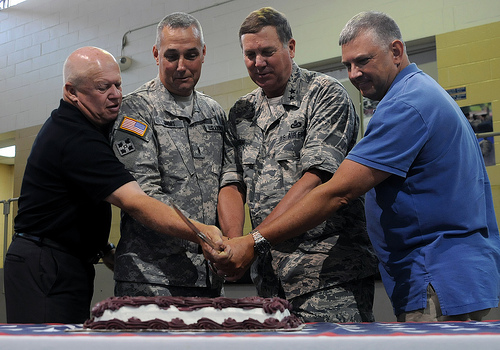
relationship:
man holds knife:
[4, 42, 226, 317] [171, 204, 220, 252]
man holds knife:
[109, 12, 226, 298] [171, 204, 220, 252]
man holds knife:
[218, 6, 380, 323] [171, 204, 220, 252]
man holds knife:
[212, 13, 500, 324] [171, 204, 220, 252]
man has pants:
[4, 51, 240, 300] [1, 235, 98, 325]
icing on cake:
[86, 285, 301, 339] [66, 267, 310, 334]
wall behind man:
[6, 2, 494, 309] [212, 13, 500, 324]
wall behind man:
[6, 2, 494, 309] [4, 42, 226, 317]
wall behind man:
[6, 2, 494, 309] [109, 12, 226, 298]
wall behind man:
[6, 2, 494, 309] [218, 6, 380, 323]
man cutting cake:
[212, 13, 500, 324] [83, 295, 307, 330]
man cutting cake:
[218, 6, 380, 323] [83, 295, 307, 330]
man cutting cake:
[109, 12, 226, 298] [83, 295, 307, 330]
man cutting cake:
[2, 46, 226, 323] [83, 295, 307, 330]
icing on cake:
[86, 295, 291, 328] [83, 295, 307, 330]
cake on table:
[83, 296, 302, 329] [8, 322, 442, 349]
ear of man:
[388, 36, 407, 68] [212, 13, 500, 324]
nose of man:
[350, 52, 361, 81] [212, 13, 500, 324]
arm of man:
[253, 156, 380, 236] [212, 13, 500, 324]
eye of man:
[356, 55, 371, 65] [212, 13, 500, 324]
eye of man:
[343, 62, 351, 69] [212, 13, 500, 324]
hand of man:
[221, 236, 256, 266] [331, 9, 498, 320]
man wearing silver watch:
[212, 13, 500, 324] [249, 227, 272, 257]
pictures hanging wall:
[455, 87, 499, 159] [0, 2, 482, 262]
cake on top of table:
[91, 287, 297, 336] [310, 315, 397, 340]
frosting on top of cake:
[90, 303, 288, 324] [61, 262, 287, 347]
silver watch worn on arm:
[250, 230, 272, 256] [219, 109, 422, 276]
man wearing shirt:
[344, 60, 484, 314] [309, 67, 499, 320]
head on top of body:
[62, 45, 122, 126] [1, 45, 224, 323]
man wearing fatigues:
[109, 12, 226, 298] [151, 103, 369, 236]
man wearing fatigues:
[218, 6, 380, 323] [151, 103, 369, 236]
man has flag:
[73, 0, 253, 307] [116, 114, 149, 139]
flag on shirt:
[116, 114, 149, 139] [111, 71, 227, 286]